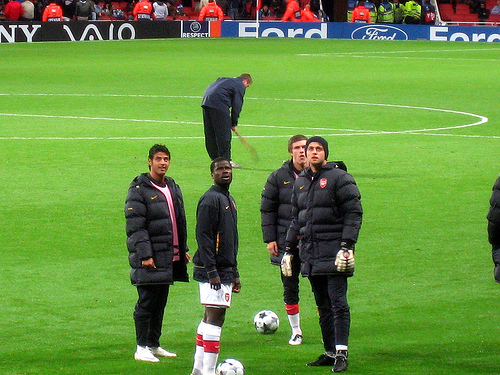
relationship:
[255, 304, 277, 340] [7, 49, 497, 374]
soccer ball on ground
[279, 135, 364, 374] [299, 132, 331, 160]
man wearing hat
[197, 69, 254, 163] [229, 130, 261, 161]
man has bat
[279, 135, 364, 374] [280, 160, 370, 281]
man wearing jacket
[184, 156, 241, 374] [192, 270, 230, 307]
man wearing shorts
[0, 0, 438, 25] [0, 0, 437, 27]
people in stands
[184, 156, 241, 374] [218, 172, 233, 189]
man has goatee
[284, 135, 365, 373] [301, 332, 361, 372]
man wearing shoes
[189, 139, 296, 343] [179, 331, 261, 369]
man wears socks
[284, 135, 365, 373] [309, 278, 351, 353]
man wears pants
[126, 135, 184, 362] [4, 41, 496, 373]
man on soccer field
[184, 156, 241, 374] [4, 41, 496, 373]
man on soccer field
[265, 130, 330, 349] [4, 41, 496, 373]
man on soccer field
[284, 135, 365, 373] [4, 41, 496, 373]
man on soccer field